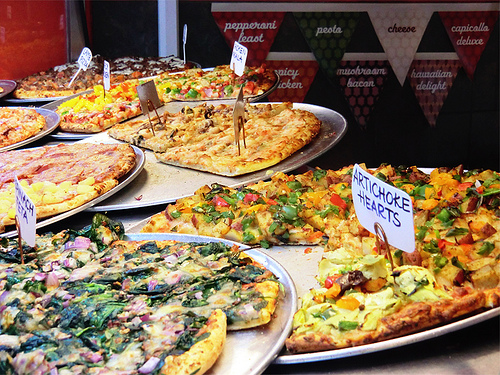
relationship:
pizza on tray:
[105, 111, 308, 233] [59, 101, 346, 214]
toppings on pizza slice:
[4, 175, 89, 216] [1, 174, 117, 231]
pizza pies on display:
[0, 55, 496, 374] [2, 51, 481, 370]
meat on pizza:
[31, 70, 91, 86] [2, 223, 283, 374]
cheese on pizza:
[21, 49, 183, 97] [2, 223, 283, 374]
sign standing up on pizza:
[350, 169, 412, 254] [163, 159, 499, 355]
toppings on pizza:
[197, 183, 312, 248] [184, 179, 471, 247]